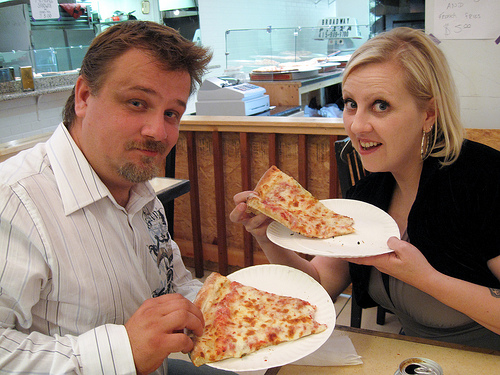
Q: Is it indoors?
A: Yes, it is indoors.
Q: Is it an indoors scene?
A: Yes, it is indoors.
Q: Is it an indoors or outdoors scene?
A: It is indoors.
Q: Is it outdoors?
A: No, it is indoors.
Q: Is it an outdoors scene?
A: No, it is indoors.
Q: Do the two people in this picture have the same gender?
A: No, they are both male and female.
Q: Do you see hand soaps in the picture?
A: No, there are no hand soaps.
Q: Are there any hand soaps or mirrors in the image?
A: No, there are no hand soaps or mirrors.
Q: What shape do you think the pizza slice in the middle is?
A: The pizza slice is triangular.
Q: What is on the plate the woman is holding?
A: The pizza slice is on the plate.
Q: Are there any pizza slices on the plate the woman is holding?
A: Yes, there is a pizza slice on the plate.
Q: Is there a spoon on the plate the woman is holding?
A: No, there is a pizza slice on the plate.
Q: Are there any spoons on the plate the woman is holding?
A: No, there is a pizza slice on the plate.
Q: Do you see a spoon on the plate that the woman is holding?
A: No, there is a pizza slice on the plate.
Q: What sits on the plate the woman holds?
A: The pizza slice sits on the plate.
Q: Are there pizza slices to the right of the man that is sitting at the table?
A: Yes, there is a pizza slice to the right of the man.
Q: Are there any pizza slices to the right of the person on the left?
A: Yes, there is a pizza slice to the right of the man.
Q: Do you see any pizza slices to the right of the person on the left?
A: Yes, there is a pizza slice to the right of the man.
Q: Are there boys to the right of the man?
A: No, there is a pizza slice to the right of the man.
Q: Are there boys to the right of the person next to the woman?
A: No, there is a pizza slice to the right of the man.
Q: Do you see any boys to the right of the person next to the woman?
A: No, there is a pizza slice to the right of the man.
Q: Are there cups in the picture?
A: No, there are no cups.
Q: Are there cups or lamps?
A: No, there are no cups or lamps.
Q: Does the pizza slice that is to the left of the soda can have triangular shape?
A: Yes, the pizza slice is triangular.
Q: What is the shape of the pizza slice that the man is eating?
A: The pizza slice is triangular.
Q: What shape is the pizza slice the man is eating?
A: The pizza slice is triangular.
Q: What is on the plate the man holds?
A: The pizza slice is on the plate.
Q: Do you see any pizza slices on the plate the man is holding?
A: Yes, there is a pizza slice on the plate.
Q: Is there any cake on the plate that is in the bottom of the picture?
A: No, there is a pizza slice on the plate.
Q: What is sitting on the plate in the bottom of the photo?
A: The pizza slice is sitting on the plate.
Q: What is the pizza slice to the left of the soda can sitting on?
A: The pizza slice is sitting on the plate.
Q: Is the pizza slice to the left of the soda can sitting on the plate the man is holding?
A: Yes, the pizza slice is sitting on the plate.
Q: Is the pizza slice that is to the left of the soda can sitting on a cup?
A: No, the pizza slice is sitting on the plate.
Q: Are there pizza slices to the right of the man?
A: Yes, there is a pizza slice to the right of the man.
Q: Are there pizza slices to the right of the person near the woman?
A: Yes, there is a pizza slice to the right of the man.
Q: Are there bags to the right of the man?
A: No, there is a pizza slice to the right of the man.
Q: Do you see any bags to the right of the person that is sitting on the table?
A: No, there is a pizza slice to the right of the man.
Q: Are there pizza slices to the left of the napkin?
A: Yes, there is a pizza slice to the left of the napkin.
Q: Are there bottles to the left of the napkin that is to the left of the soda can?
A: No, there is a pizza slice to the left of the napkin.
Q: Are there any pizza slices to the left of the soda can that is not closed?
A: Yes, there is a pizza slice to the left of the soda can.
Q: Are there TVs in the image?
A: No, there are no tvs.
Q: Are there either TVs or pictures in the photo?
A: No, there are no TVs or pictures.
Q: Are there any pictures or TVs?
A: No, there are no TVs or pictures.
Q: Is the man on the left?
A: Yes, the man is on the left of the image.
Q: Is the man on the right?
A: No, the man is on the left of the image.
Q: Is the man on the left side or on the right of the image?
A: The man is on the left of the image.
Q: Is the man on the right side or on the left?
A: The man is on the left of the image.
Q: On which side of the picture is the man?
A: The man is on the left of the image.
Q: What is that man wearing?
A: The man is wearing a shirt.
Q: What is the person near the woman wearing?
A: The man is wearing a shirt.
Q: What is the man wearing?
A: The man is wearing a shirt.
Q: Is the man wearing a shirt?
A: Yes, the man is wearing a shirt.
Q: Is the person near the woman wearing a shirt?
A: Yes, the man is wearing a shirt.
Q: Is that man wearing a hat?
A: No, the man is wearing a shirt.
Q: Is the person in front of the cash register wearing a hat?
A: No, the man is wearing a shirt.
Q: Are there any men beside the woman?
A: Yes, there is a man beside the woman.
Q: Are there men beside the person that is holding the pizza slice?
A: Yes, there is a man beside the woman.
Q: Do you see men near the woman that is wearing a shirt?
A: Yes, there is a man near the woman.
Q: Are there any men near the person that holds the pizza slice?
A: Yes, there is a man near the woman.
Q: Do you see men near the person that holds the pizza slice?
A: Yes, there is a man near the woman.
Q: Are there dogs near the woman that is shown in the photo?
A: No, there is a man near the woman.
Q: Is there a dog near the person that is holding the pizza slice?
A: No, there is a man near the woman.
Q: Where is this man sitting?
A: The man is sitting at the table.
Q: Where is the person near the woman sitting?
A: The man is sitting at the table.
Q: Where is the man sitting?
A: The man is sitting at the table.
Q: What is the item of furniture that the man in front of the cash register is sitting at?
A: The piece of furniture is a table.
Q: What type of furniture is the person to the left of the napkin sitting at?
A: The man is sitting at the table.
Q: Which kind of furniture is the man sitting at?
A: The man is sitting at the table.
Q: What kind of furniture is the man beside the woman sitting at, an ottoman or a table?
A: The man is sitting at a table.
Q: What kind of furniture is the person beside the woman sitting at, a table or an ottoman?
A: The man is sitting at a table.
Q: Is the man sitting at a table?
A: Yes, the man is sitting at a table.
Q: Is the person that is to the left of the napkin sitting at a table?
A: Yes, the man is sitting at a table.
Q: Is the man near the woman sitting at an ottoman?
A: No, the man is sitting at a table.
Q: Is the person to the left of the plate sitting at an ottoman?
A: No, the man is sitting at a table.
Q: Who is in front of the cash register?
A: The man is in front of the cash register.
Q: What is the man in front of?
A: The man is in front of the cash register.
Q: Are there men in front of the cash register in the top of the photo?
A: Yes, there is a man in front of the cash register.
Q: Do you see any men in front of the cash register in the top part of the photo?
A: Yes, there is a man in front of the cash register.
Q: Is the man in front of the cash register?
A: Yes, the man is in front of the cash register.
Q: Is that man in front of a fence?
A: No, the man is in front of the cash register.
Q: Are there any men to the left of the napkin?
A: Yes, there is a man to the left of the napkin.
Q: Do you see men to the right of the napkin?
A: No, the man is to the left of the napkin.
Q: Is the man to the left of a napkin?
A: Yes, the man is to the left of a napkin.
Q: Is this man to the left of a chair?
A: No, the man is to the left of a napkin.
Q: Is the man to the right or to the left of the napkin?
A: The man is to the left of the napkin.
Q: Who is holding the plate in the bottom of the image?
A: The man is holding the plate.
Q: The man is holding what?
A: The man is holding the plate.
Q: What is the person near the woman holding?
A: The man is holding the plate.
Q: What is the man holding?
A: The man is holding the plate.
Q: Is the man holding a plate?
A: Yes, the man is holding a plate.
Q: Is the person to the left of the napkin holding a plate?
A: Yes, the man is holding a plate.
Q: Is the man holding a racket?
A: No, the man is holding a plate.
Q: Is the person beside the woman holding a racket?
A: No, the man is holding a plate.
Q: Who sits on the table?
A: The man sits on the table.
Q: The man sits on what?
A: The man sits on the table.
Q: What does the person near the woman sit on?
A: The man sits on the table.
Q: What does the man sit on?
A: The man sits on the table.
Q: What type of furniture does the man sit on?
A: The man sits on the table.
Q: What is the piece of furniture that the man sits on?
A: The piece of furniture is a table.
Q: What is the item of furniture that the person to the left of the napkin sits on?
A: The piece of furniture is a table.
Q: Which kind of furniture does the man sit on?
A: The man sits on the table.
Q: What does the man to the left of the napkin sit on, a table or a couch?
A: The man sits on a table.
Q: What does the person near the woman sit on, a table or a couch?
A: The man sits on a table.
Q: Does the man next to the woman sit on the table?
A: Yes, the man sits on the table.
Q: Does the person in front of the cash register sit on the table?
A: Yes, the man sits on the table.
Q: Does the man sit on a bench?
A: No, the man sits on the table.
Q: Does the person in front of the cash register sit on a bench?
A: No, the man sits on the table.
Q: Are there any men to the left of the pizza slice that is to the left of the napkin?
A: Yes, there is a man to the left of the pizza slice.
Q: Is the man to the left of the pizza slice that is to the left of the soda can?
A: Yes, the man is to the left of the pizza slice.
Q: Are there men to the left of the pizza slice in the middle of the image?
A: Yes, there is a man to the left of the pizza slice.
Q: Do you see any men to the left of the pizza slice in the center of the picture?
A: Yes, there is a man to the left of the pizza slice.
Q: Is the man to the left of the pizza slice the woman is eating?
A: Yes, the man is to the left of the pizza slice.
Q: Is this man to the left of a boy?
A: No, the man is to the left of the pizza slice.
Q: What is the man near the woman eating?
A: The man is eating a pizza slice.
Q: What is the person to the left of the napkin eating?
A: The man is eating a pizza slice.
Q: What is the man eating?
A: The man is eating a pizza slice.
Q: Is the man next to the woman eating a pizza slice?
A: Yes, the man is eating a pizza slice.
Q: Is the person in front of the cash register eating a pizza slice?
A: Yes, the man is eating a pizza slice.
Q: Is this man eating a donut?
A: No, the man is eating a pizza slice.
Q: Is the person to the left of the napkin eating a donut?
A: No, the man is eating a pizza slice.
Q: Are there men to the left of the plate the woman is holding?
A: Yes, there is a man to the left of the plate.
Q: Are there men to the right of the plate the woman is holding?
A: No, the man is to the left of the plate.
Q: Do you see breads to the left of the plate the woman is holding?
A: No, there is a man to the left of the plate.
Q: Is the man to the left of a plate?
A: Yes, the man is to the left of a plate.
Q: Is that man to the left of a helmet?
A: No, the man is to the left of a plate.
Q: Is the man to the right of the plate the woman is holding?
A: No, the man is to the left of the plate.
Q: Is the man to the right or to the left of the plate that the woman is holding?
A: The man is to the left of the plate.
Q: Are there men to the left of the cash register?
A: Yes, there is a man to the left of the cash register.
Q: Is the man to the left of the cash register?
A: Yes, the man is to the left of the cash register.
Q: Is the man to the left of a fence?
A: No, the man is to the left of the cash register.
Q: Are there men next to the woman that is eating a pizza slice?
A: Yes, there is a man next to the woman.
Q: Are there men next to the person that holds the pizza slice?
A: Yes, there is a man next to the woman.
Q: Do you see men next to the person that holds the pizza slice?
A: Yes, there is a man next to the woman.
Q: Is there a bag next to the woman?
A: No, there is a man next to the woman.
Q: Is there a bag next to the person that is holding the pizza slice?
A: No, there is a man next to the woman.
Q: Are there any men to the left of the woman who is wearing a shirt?
A: Yes, there is a man to the left of the woman.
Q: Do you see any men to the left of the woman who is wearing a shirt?
A: Yes, there is a man to the left of the woman.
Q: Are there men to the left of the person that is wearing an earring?
A: Yes, there is a man to the left of the woman.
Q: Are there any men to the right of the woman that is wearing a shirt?
A: No, the man is to the left of the woman.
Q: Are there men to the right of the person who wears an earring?
A: No, the man is to the left of the woman.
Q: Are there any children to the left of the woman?
A: No, there is a man to the left of the woman.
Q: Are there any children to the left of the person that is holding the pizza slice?
A: No, there is a man to the left of the woman.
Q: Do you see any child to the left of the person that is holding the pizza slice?
A: No, there is a man to the left of the woman.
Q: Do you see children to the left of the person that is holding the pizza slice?
A: No, there is a man to the left of the woman.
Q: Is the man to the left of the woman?
A: Yes, the man is to the left of the woman.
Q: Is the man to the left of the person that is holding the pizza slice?
A: Yes, the man is to the left of the woman.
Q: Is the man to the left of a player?
A: No, the man is to the left of the woman.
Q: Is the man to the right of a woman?
A: No, the man is to the left of a woman.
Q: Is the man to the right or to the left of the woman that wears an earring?
A: The man is to the left of the woman.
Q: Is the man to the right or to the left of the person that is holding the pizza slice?
A: The man is to the left of the woman.